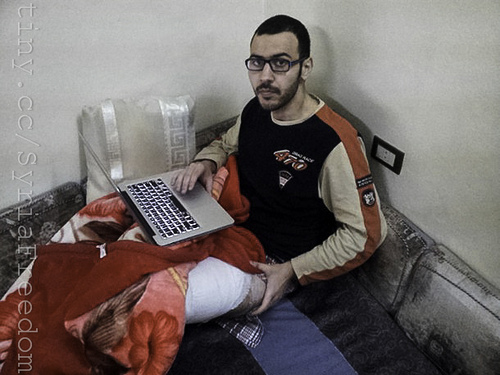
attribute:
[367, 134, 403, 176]
outlet — black, small, white, electrical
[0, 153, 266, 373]
bedspread — floral, red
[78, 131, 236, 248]
laptop — open, silver, black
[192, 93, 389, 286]
shirt — long sleeved, orange, black, wrinkled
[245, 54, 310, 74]
glasses — black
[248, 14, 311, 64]
hair — black, short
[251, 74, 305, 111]
beard — short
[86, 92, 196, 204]
cushion — silver, ivory, square, white, silvery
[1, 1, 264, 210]
wall — white, solid color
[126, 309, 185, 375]
flower — red, large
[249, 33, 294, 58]
forehead — wrinkled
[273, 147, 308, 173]
logo — red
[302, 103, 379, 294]
stripe — orange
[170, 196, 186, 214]
spacebar — black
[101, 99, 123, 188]
strip — satin